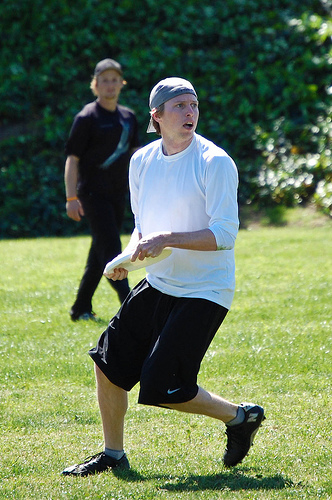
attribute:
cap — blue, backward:
[93, 58, 121, 78]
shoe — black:
[223, 399, 264, 467]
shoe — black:
[62, 451, 129, 477]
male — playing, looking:
[63, 77, 263, 480]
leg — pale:
[93, 281, 173, 449]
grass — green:
[1, 226, 330, 500]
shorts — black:
[89, 279, 229, 407]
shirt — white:
[104, 129, 239, 309]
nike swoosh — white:
[165, 385, 182, 395]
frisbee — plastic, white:
[104, 244, 173, 280]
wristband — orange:
[68, 194, 78, 204]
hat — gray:
[148, 74, 196, 134]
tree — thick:
[2, 2, 331, 239]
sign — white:
[248, 412, 259, 424]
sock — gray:
[229, 406, 248, 428]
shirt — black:
[66, 101, 139, 205]